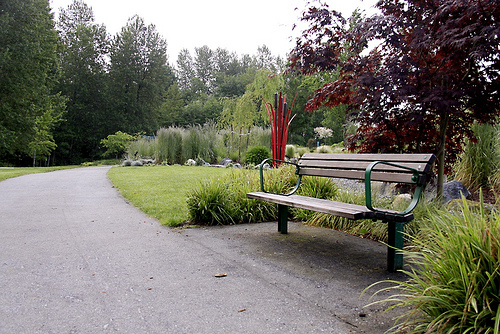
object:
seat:
[245, 190, 415, 223]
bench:
[245, 153, 437, 273]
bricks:
[245, 146, 445, 274]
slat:
[246, 191, 415, 224]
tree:
[265, 0, 499, 200]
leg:
[274, 204, 291, 234]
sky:
[50, 0, 383, 55]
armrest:
[363, 153, 436, 216]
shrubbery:
[0, 0, 500, 166]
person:
[314, 134, 326, 148]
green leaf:
[358, 187, 500, 334]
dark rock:
[423, 180, 498, 214]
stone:
[230, 163, 242, 168]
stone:
[224, 158, 233, 166]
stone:
[185, 159, 196, 167]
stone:
[121, 158, 153, 166]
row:
[120, 155, 284, 165]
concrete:
[0, 164, 417, 334]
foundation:
[179, 207, 427, 322]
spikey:
[257, 90, 296, 170]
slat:
[296, 151, 435, 186]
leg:
[386, 222, 405, 272]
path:
[0, 163, 500, 334]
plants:
[125, 117, 223, 163]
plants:
[183, 150, 335, 227]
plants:
[265, 0, 500, 210]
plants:
[359, 187, 500, 334]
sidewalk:
[1, 166, 428, 334]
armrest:
[258, 156, 302, 196]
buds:
[274, 0, 499, 190]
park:
[0, 0, 500, 334]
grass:
[105, 120, 498, 334]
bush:
[359, 182, 500, 329]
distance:
[0, 112, 493, 198]